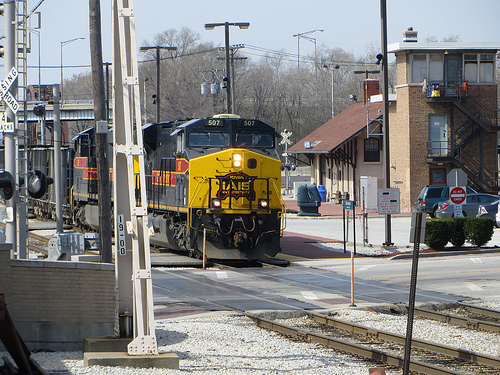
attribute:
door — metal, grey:
[425, 109, 451, 157]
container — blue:
[315, 181, 325, 201]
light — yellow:
[217, 134, 280, 181]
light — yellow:
[216, 134, 265, 184]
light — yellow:
[208, 123, 257, 190]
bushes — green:
[390, 174, 499, 301]